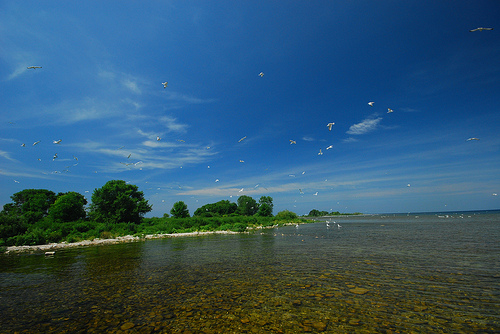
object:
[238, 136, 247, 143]
bird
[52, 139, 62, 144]
bird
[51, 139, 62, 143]
bird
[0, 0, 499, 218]
sky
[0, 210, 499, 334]
water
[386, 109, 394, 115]
bird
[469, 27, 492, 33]
bird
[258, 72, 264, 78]
bird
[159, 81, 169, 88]
bird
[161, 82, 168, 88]
bird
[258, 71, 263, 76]
bird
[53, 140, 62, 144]
bird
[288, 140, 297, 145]
bird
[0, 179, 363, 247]
greenery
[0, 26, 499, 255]
birds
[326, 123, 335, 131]
white bird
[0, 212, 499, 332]
rocks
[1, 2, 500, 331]
bright/clear day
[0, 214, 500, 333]
clear water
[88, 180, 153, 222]
tree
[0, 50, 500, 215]
clouds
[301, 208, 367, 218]
land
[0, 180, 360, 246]
bushes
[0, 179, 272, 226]
trees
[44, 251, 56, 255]
log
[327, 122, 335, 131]
bird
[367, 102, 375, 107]
bird